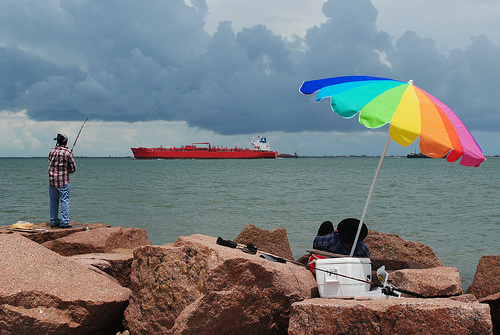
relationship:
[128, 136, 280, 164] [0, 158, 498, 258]
ship in water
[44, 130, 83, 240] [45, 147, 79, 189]
man in shirt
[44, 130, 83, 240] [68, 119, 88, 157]
man holding pole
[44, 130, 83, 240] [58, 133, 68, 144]
man wearing bandana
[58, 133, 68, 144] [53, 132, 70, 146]
bandana on head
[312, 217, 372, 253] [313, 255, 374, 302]
man on cooler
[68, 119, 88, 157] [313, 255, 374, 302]
pole near cooler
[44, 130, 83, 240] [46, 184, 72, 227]
man wearing jeans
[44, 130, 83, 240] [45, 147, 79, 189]
man wearing shirt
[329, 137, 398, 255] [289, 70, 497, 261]
pole under umbrella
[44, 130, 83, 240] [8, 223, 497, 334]
man on rocks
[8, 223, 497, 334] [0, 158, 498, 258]
rocks by sea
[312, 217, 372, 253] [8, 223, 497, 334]
man on rocks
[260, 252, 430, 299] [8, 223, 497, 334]
rod across rocks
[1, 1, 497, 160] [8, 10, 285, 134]
sky with clouds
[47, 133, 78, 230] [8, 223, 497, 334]
man on rocks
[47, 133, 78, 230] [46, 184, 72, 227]
man wearing jeans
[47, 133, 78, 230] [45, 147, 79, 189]
man wearing shirt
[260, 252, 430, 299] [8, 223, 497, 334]
fish reel on ground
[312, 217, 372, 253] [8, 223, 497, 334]
person on rocks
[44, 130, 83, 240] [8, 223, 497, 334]
man on shore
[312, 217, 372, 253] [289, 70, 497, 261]
person under umbrella